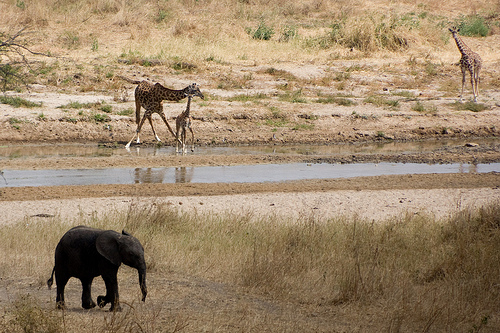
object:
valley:
[2, 0, 499, 333]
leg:
[129, 110, 153, 141]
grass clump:
[38, 112, 46, 120]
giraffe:
[124, 78, 205, 154]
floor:
[3, 140, 499, 190]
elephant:
[45, 224, 149, 314]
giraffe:
[448, 26, 484, 103]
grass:
[0, 204, 499, 333]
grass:
[0, 0, 499, 136]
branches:
[212, 219, 498, 305]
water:
[0, 140, 499, 190]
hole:
[0, 126, 499, 194]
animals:
[45, 224, 147, 312]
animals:
[125, 77, 206, 155]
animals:
[447, 26, 483, 102]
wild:
[5, 22, 498, 312]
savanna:
[3, 0, 499, 333]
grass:
[245, 19, 278, 42]